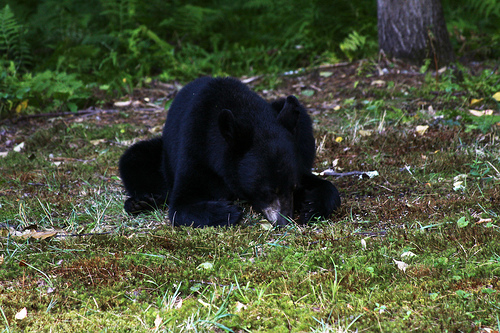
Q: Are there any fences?
A: No, there are no fences.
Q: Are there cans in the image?
A: No, there are no cans.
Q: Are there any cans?
A: No, there are no cans.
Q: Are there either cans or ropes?
A: No, there are no cans or ropes.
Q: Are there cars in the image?
A: No, there are no cars.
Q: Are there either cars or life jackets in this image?
A: No, there are no cars or life jackets.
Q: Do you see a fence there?
A: No, there are no fences.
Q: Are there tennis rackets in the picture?
A: No, there are no tennis rackets.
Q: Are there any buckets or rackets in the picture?
A: No, there are no rackets or buckets.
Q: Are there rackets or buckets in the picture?
A: No, there are no rackets or buckets.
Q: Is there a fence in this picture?
A: No, there are no fences.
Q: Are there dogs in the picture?
A: No, there are no dogs.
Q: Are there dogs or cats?
A: No, there are no dogs or cats.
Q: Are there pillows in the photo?
A: No, there are no pillows.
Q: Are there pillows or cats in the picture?
A: No, there are no pillows or cats.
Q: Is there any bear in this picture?
A: Yes, there is a bear.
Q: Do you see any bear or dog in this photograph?
A: Yes, there is a bear.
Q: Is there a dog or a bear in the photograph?
A: Yes, there is a bear.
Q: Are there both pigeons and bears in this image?
A: No, there is a bear but no pigeons.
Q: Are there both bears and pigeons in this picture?
A: No, there is a bear but no pigeons.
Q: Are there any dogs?
A: No, there are no dogs.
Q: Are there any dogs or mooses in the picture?
A: No, there are no dogs or mooses.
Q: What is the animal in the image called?
A: The animal is a bear.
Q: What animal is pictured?
A: The animal is a bear.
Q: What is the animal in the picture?
A: The animal is a bear.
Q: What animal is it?
A: The animal is a bear.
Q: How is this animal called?
A: This is a bear.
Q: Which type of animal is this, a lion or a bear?
A: This is a bear.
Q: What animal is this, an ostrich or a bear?
A: This is a bear.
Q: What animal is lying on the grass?
A: The bear is lying on the grass.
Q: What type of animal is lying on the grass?
A: The animal is a bear.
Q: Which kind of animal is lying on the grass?
A: The animal is a bear.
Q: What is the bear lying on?
A: The bear is lying on the grass.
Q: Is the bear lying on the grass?
A: Yes, the bear is lying on the grass.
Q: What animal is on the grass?
A: The bear is on the grass.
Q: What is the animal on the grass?
A: The animal is a bear.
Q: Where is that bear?
A: The bear is on the grass.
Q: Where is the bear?
A: The bear is on the grass.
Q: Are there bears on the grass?
A: Yes, there is a bear on the grass.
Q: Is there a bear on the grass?
A: Yes, there is a bear on the grass.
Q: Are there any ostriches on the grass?
A: No, there is a bear on the grass.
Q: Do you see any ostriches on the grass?
A: No, there is a bear on the grass.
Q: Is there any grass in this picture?
A: Yes, there is grass.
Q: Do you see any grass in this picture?
A: Yes, there is grass.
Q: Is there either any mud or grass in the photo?
A: Yes, there is grass.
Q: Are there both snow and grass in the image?
A: No, there is grass but no snow.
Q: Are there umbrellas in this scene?
A: No, there are no umbrellas.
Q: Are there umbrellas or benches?
A: No, there are no umbrellas or benches.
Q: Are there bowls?
A: No, there are no bowls.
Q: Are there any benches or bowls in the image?
A: No, there are no bowls or benches.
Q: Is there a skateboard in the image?
A: No, there are no skateboards.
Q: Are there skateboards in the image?
A: No, there are no skateboards.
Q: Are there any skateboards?
A: No, there are no skateboards.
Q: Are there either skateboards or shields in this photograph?
A: No, there are no skateboards or shields.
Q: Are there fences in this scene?
A: No, there are no fences.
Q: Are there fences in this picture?
A: No, there are no fences.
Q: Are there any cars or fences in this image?
A: No, there are no fences or cars.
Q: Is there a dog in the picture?
A: No, there are no dogs.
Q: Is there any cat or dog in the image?
A: No, there are no dogs or cats.